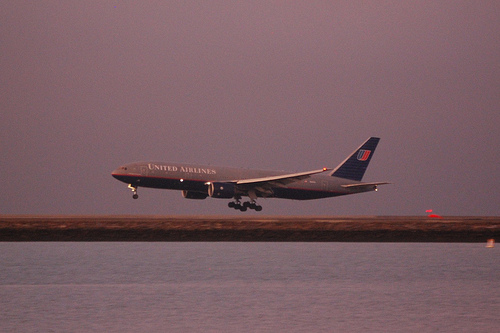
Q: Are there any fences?
A: No, there are no fences.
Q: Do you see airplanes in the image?
A: Yes, there is an airplane.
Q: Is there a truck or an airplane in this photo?
A: Yes, there is an airplane.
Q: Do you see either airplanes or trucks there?
A: Yes, there is an airplane.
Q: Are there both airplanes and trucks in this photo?
A: No, there is an airplane but no trucks.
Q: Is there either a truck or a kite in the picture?
A: No, there are no kites or trucks.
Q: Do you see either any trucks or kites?
A: No, there are no kites or trucks.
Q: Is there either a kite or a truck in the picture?
A: No, there are no kites or trucks.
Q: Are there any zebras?
A: No, there are no zebras.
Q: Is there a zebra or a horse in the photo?
A: No, there are no zebras or horses.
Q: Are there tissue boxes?
A: No, there are no tissue boxes.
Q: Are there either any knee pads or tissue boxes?
A: No, there are no tissue boxes or knee pads.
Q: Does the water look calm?
A: Yes, the water is calm.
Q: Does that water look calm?
A: Yes, the water is calm.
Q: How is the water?
A: The water is calm.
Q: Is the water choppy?
A: No, the water is calm.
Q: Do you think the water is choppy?
A: No, the water is calm.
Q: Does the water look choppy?
A: No, the water is calm.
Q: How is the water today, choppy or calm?
A: The water is calm.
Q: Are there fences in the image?
A: No, there are no fences.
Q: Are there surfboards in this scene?
A: No, there are no surfboards.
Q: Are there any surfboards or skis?
A: No, there are no surfboards or skis.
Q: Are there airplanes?
A: Yes, there is an airplane.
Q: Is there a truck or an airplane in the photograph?
A: Yes, there is an airplane.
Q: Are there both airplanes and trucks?
A: No, there is an airplane but no trucks.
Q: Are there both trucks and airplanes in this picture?
A: No, there is an airplane but no trucks.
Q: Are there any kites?
A: No, there are no kites.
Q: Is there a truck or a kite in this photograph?
A: No, there are no kites or trucks.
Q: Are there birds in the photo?
A: No, there are no birds.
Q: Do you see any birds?
A: No, there are no birds.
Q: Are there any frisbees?
A: No, there are no frisbees.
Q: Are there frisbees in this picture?
A: No, there are no frisbees.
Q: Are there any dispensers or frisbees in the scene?
A: No, there are no frisbees or dispensers.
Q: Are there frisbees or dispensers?
A: No, there are no frisbees or dispensers.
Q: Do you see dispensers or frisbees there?
A: No, there are no frisbees or dispensers.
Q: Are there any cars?
A: No, there are no cars.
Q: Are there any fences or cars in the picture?
A: No, there are no cars or fences.